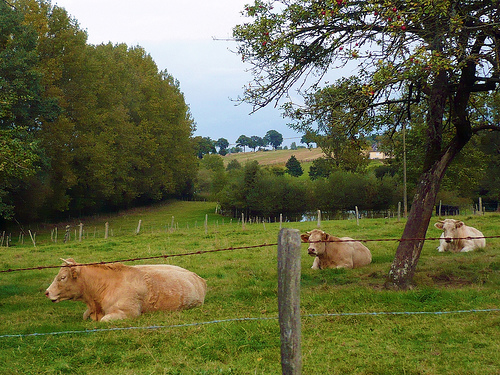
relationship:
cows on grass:
[299, 225, 374, 270] [3, 196, 498, 372]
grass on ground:
[310, 319, 492, 373] [430, 265, 467, 284]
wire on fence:
[0, 234, 496, 274] [2, 227, 498, 371]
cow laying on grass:
[26, 240, 243, 362] [321, 319, 459, 350]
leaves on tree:
[132, 182, 139, 191] [3, 0, 208, 214]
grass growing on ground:
[3, 196, 498, 372] [3, 196, 498, 373]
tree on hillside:
[262, 128, 282, 153] [215, 147, 336, 181]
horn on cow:
[52, 252, 77, 274] [25, 231, 225, 347]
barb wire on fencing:
[309, 234, 498, 247] [4, 231, 498, 374]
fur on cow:
[109, 277, 166, 294] [38, 249, 212, 332]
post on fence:
[267, 216, 323, 313] [2, 195, 498, 373]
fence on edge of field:
[0, 235, 498, 375] [218, 274, 499, 371]